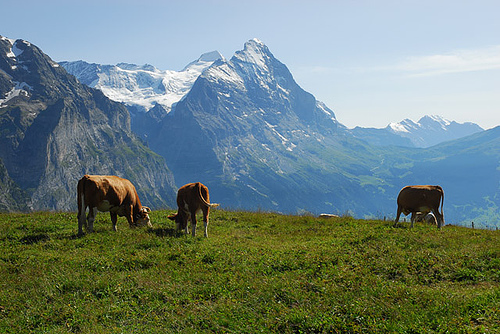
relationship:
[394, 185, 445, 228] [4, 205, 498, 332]
cattle on hill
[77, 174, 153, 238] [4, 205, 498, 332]
cattle on hill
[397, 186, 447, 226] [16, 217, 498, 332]
cows on top of hill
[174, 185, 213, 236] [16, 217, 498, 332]
cows on top of hill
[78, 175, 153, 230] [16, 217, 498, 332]
cows on top of hill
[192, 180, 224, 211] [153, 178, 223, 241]
tail of cow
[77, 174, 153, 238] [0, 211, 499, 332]
cattle grazing in grass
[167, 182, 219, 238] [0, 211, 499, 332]
cattle grazing in grass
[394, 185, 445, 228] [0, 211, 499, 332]
cattle grazing in grass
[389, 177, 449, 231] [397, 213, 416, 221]
cattle eating of ground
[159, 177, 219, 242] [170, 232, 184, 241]
cattle eating of ground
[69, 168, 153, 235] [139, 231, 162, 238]
cattle eating of ground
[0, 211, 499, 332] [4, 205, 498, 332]
grass on top of hill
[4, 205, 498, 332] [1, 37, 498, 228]
hill near a mountain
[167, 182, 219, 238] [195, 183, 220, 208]
cattle wagging tail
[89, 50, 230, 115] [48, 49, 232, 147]
snow on mountain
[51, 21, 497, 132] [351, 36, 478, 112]
sky has clouds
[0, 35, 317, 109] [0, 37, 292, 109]
peak has snow